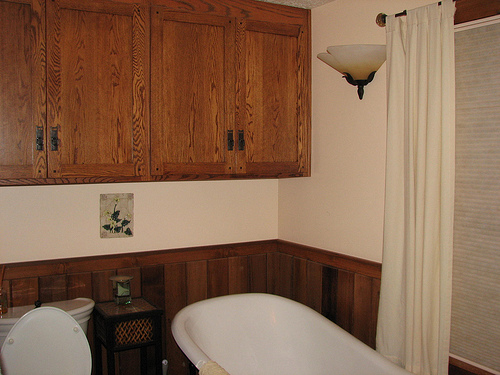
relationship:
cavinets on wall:
[1, 7, 309, 178] [287, 77, 387, 227]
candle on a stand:
[106, 271, 138, 312] [90, 293, 162, 373]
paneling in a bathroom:
[34, 262, 61, 299] [10, 33, 493, 373]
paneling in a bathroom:
[137, 257, 164, 314] [10, 33, 493, 373]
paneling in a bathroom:
[162, 255, 187, 316] [10, 33, 493, 373]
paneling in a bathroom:
[182, 250, 213, 302] [10, 33, 493, 373]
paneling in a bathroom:
[206, 254, 259, 286] [10, 33, 493, 373]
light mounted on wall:
[312, 26, 392, 93] [307, 16, 390, 248]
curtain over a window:
[382, 8, 450, 373] [387, 10, 498, 373]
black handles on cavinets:
[226, 131, 246, 149] [1, 7, 309, 178]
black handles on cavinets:
[32, 122, 60, 152] [1, 7, 309, 178]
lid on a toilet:
[20, 298, 73, 339] [4, 286, 69, 366]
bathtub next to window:
[148, 265, 412, 374] [372, 32, 480, 276]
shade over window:
[449, 15, 498, 373] [395, 48, 485, 363]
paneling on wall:
[2, 236, 384, 289] [2, 173, 384, 341]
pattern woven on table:
[114, 318, 158, 344] [101, 277, 168, 354]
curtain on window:
[379, 8, 450, 374] [449, 20, 497, 374]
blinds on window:
[367, 23, 460, 373] [387, 8, 484, 368]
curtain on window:
[379, 8, 450, 374] [387, 8, 484, 368]